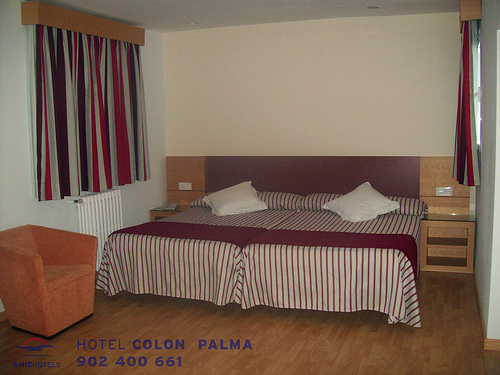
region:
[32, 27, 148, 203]
red, brown, and white striped curtains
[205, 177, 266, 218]
white throw pillow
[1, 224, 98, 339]
orange side chair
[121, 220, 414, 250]
maroon folded blanket on a bed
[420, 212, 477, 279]
wooden side table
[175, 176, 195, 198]
white electrical receptor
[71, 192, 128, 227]
white wall heater radiator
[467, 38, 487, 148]
window on wall in bedroom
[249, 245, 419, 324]
red and white striped sheets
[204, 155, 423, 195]
maroon headboard on bed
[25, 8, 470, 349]
A hotel room.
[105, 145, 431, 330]
Two average sized beds pushed together.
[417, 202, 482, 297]
A nightstand made from wood.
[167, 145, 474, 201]
A wooden headboard.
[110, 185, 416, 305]
A bedspread with red stripes on it.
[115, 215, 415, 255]
A red blanket going across the bottom half of each bed.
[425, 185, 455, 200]
An electrical outlet.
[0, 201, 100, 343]
A small chair.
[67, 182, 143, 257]
A radiator underneath the window.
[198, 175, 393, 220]
Two white pillows.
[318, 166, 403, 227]
a white square pillow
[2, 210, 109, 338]
an unattractive orange chair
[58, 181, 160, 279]
a white heating element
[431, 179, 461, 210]
a white electrical outlet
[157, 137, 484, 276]
a red and wood headboard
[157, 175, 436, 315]
two full beds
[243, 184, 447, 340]
red and white striped comforter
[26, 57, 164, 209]
multicolored striped curtains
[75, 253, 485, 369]
clean shiny wooden floors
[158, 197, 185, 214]
a silver home phone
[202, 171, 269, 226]
white pillow on bed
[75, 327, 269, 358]
Hotel colon Palma is the hotel name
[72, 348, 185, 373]
Hotel telephone number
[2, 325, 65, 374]
Hotel Logo in corner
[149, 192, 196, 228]
nightstand beside bed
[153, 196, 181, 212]
telephone on night stand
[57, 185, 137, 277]
Radiator heat in room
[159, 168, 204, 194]
Electrical outlet in wall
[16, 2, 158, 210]
Curtains covering the window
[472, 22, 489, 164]
Light coming through the window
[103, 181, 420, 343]
Two beds pulled together.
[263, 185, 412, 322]
Red and white striped bed spread.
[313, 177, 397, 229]
A white throw pillow on bed.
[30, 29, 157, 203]
Red, gray and burgundy curtains on window.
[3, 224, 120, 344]
A brown club chair.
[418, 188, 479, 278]
Nightstand next to bed.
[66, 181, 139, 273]
Radiator on wall under curtains.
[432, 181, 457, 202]
Electrical outlet on wall above nightstand.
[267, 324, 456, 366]
Wood floor in room.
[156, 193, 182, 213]
Telephone sitting on nightstand.